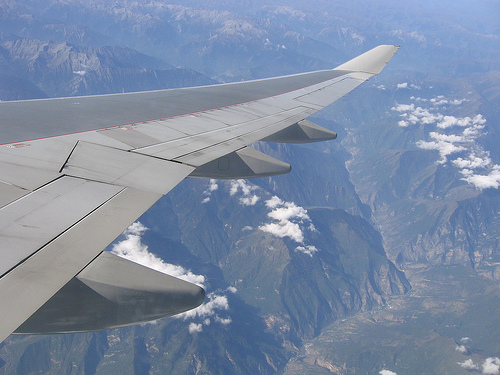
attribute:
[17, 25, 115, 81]
sun — shines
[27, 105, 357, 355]
tanks — three, spare, fuel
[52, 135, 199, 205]
spoiler — metal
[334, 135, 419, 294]
chasm — small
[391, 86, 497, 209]
formation — small, cloud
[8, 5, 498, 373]
chain — large, mountain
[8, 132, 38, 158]
light — guide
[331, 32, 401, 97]
tip — long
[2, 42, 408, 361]
wing — jet, modern, large, gray, slanted, curves upwards, long, silver, jet's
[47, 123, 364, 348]
bottom — white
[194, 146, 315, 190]
bottom — white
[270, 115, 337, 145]
bottom — white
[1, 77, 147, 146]
front — grey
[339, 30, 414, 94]
tip — curved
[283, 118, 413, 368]
creek — barren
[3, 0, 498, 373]
landcape — gray, mountainous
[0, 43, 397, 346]
wings — gray, metal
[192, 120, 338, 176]
engines — gray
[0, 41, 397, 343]
jet — grooves, metal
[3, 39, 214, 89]
mountain top — jagged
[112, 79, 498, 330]
clouds — white, fluffy